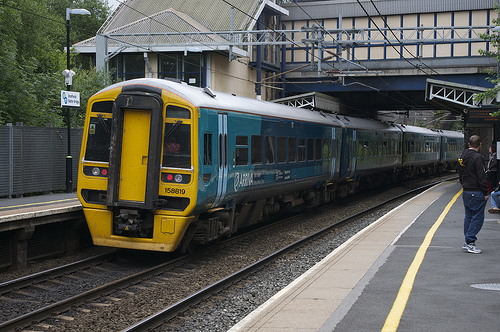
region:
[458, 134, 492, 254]
man wearing a black coat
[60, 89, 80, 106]
small white sign on a black pole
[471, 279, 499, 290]
man hole cover on the walkway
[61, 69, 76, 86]
gray box on a black pole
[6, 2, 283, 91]
cords going across the trees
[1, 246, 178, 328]
set of train tracks the train is on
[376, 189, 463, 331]
yellow line painted on the walkway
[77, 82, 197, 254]
yellow part of the train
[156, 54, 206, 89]
window in a building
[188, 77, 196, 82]
small white sign on a window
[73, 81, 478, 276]
blue and yellow train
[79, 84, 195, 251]
yellow front part of train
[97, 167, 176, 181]
small red front lights of train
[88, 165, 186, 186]
small white front lights of train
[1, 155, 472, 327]
large black train tracks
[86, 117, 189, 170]
black windshields of large train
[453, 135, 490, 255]
man wearing black jacket standing in the platform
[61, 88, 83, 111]
white signboard in large black pole in the platform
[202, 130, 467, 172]
black windows on left side of large train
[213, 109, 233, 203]
light blue door on left side of train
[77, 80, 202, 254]
yellow front of passenger train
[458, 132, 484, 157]
man with short dark hair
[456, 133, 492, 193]
one man wearing dark long sleeved shirt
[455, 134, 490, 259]
one man wearing blue pants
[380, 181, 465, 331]
yellow line on black pavement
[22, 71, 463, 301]
one green and yellow train on tracks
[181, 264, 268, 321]
section of gray gravel along tracks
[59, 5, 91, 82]
one black and gray metal street lamp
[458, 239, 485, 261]
white sneaker on black pavement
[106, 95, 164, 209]
one yellow and black rectangular doorway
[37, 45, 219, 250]
the front of the train is yellow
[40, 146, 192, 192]
the headlights are off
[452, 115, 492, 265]
man standing on the platform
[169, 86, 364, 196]
the side of the train is aqua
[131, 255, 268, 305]
gravel on the tracks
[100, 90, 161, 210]
the door is closed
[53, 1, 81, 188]
the pole is tall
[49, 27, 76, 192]
the pole is black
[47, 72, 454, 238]
the train is at the station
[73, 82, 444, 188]
the train has passengers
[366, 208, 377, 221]
edge of a road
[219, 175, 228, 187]
part of a train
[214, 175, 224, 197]
edge of a train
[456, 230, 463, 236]
part of a shoe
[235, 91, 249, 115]
part of a house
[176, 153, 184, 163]
edge of a train